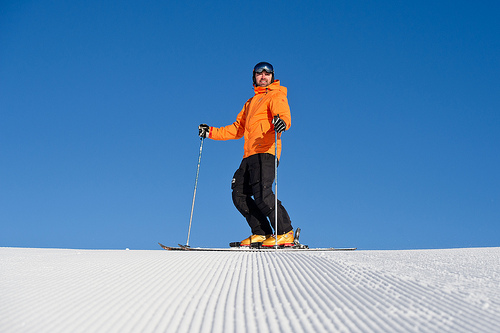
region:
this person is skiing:
[144, 37, 406, 294]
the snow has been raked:
[8, 245, 498, 330]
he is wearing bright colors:
[173, 35, 365, 285]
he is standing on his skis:
[145, 33, 411, 320]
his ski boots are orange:
[228, 225, 315, 247]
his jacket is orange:
[193, 52, 316, 161]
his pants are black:
[216, 154, 323, 255]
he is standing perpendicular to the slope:
[138, 7, 425, 285]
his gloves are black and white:
[186, 109, 332, 148]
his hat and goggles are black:
[246, 49, 295, 85]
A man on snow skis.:
[158, 58, 358, 252]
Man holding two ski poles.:
[176, 113, 281, 249]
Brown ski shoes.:
[242, 227, 294, 248]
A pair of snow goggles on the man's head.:
[249, 60, 275, 75]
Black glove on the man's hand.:
[269, 113, 286, 135]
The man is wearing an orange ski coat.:
[208, 78, 293, 162]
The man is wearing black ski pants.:
[230, 153, 292, 232]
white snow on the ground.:
[0, 246, 498, 331]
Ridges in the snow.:
[1, 246, 497, 331]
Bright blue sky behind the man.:
[0, 0, 497, 247]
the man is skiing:
[159, 28, 364, 256]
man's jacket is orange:
[209, 84, 300, 158]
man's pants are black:
[230, 152, 295, 234]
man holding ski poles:
[182, 118, 299, 256]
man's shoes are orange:
[232, 222, 301, 257]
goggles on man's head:
[246, 55, 278, 77]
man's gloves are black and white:
[187, 112, 288, 141]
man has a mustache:
[254, 73, 279, 89]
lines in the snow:
[2, 243, 497, 331]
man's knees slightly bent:
[224, 171, 279, 217]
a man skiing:
[181, 63, 335, 254]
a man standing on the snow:
[178, 62, 349, 255]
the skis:
[148, 231, 355, 254]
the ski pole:
[185, 123, 207, 249]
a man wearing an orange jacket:
[201, 60, 291, 248]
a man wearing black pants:
[201, 63, 291, 245]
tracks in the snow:
[146, 258, 486, 323]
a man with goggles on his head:
[211, 61, 301, 248]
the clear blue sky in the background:
[2, 28, 155, 242]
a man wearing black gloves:
[197, 56, 292, 169]